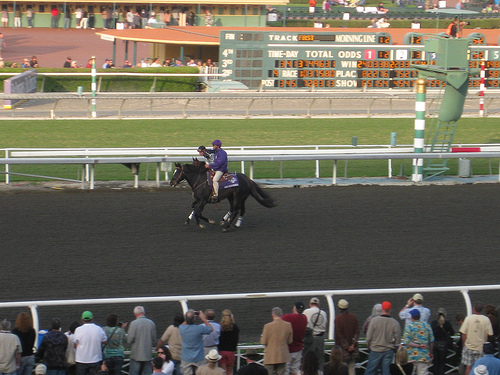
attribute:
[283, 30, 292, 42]
letter — white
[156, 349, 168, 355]
glasses — sun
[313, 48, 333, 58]
letter — white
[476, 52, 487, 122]
pole — white, red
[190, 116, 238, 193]
man — photographing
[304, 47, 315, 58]
letter — white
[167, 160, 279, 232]
horse — black, gliding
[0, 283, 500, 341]
barricade — white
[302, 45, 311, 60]
letter — white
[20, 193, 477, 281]
track — dirt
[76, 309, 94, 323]
cap — green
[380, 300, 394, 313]
cap — green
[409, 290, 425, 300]
cap — green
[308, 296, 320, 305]
cap — green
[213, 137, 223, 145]
cap — green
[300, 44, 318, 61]
letter — white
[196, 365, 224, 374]
shirt — beige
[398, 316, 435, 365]
shirt — flowered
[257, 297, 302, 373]
gentleman — older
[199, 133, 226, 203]
gentleman — older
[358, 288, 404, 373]
gentleman — older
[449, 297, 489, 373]
gentleman — older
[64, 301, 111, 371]
gentleman — older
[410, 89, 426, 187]
green/white pole — green, white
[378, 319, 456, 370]
shirt — multi-colored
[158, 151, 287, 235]
horse — brown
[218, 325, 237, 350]
shirt — black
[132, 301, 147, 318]
hair — white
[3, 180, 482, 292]
track — race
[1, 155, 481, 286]
track — horse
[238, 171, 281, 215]
tail — black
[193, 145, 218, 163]
hoodie — gray, black